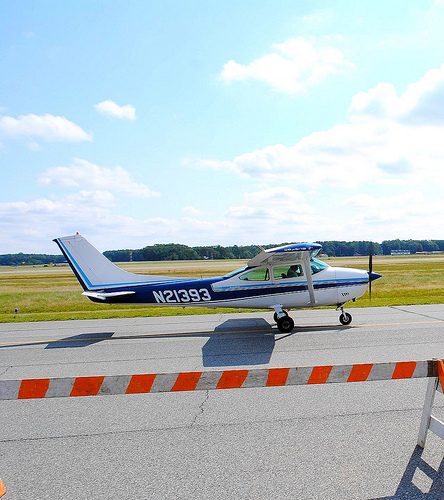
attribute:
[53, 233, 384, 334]
plane — white, single, blue, takingoff, small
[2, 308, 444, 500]
tarmac — grey, airport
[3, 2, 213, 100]
sky — blue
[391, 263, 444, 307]
grass — short, green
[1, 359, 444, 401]
sign — orange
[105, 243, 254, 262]
trees — green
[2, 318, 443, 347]
line — yellow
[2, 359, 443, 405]
barrier — striped, orange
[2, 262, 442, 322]
field — grassy